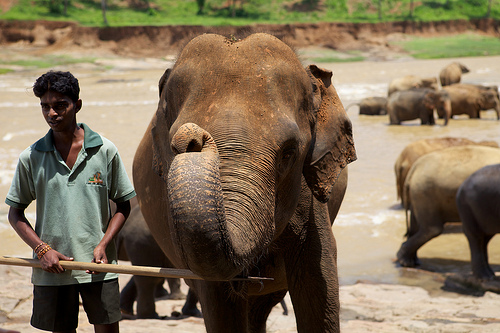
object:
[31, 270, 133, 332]
shorts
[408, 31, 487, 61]
grass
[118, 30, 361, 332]
elephant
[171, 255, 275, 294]
stick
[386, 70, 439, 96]
elephant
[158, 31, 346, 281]
head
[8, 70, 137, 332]
man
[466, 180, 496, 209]
grey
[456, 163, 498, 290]
elephant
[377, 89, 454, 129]
elephant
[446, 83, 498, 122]
elephant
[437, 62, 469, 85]
elephant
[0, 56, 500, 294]
water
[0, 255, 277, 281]
poll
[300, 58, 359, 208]
elephant ear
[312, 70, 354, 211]
mud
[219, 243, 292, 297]
mouth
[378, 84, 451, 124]
elephants